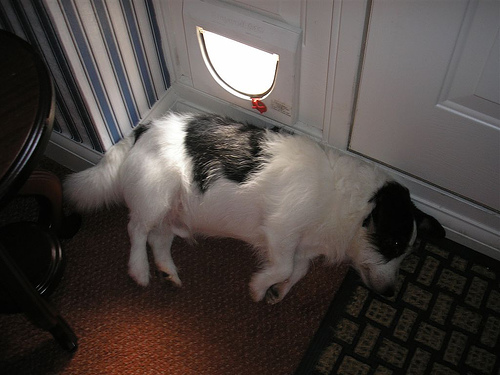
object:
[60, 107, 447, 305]
dog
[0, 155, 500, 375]
floor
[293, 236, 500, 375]
door mat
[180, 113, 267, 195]
black patch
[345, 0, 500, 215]
door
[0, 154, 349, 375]
carpet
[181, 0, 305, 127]
pet door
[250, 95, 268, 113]
lock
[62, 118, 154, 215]
tail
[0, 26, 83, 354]
table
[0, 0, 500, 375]
house